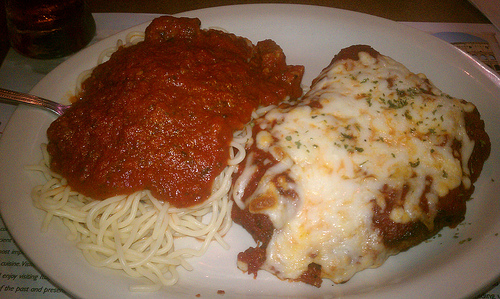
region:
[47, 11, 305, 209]
red pasta sauce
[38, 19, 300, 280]
pasta with red sauce on top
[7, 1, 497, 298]
white plate under pasta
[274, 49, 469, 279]
melted cheese on top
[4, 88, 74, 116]
gray metal fork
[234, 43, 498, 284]
chicken with melted cheese and oregano on top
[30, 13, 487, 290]
lunch on white plate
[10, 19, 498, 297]
white and light blue tablecloth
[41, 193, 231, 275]
pasta with no sauce on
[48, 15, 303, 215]
red sauce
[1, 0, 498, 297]
Spaghetti and Chicken Parmesan.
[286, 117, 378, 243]
melted cheese on food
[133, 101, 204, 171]
spaghetti sauce on noodles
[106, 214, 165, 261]
pasta on white plate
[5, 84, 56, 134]
silver utensil on plate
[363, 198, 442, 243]
marinara sauce on food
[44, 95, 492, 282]
food on white plate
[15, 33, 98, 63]
bottom of cup with dark beverage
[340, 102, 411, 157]
green herb on melted cheese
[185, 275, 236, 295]
spot of sauce on plate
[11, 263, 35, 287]
black words on white paper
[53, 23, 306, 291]
this is yummy spaghetti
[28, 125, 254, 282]
these are spaghetti noodles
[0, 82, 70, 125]
this is a fork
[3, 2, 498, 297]
this is a plate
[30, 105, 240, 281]
this is white pasta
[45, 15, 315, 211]
this is tomato sauce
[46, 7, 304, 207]
the sauce is red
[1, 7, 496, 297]
this is black and white newsprint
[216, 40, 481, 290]
this is melted mozzarella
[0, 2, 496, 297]
the plate is white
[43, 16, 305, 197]
Red spaghetti sauce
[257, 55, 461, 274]
Melted cheese on meat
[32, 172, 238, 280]
Pasta noodles on plate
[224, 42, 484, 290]
Piece of meat on plate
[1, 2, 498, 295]
White plate with food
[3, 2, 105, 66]
Glass sitting on table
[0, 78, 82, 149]
Silver utensil in pasta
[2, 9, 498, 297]
Place mat under plate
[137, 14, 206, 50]
Chunk of food in sauce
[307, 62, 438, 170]
Green vegetable seasoning on cheese